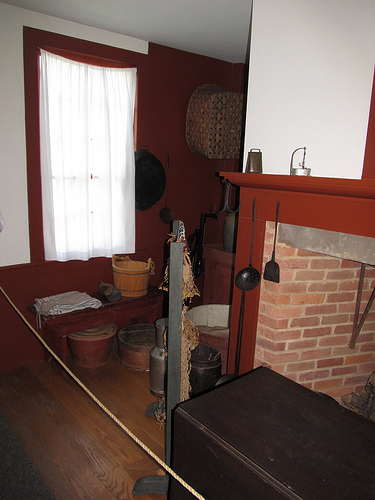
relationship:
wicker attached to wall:
[190, 66, 235, 156] [149, 67, 164, 157]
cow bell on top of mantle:
[292, 139, 322, 176] [218, 194, 363, 232]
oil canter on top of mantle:
[232, 149, 271, 180] [218, 194, 363, 232]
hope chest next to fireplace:
[192, 405, 332, 468] [247, 250, 362, 400]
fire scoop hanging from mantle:
[300, 260, 369, 396] [218, 194, 363, 232]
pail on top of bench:
[112, 260, 157, 298] [66, 303, 156, 322]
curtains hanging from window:
[33, 43, 143, 261] [48, 125, 156, 167]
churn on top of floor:
[116, 336, 178, 389] [1, 389, 150, 433]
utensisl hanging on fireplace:
[222, 198, 340, 316] [247, 250, 362, 400]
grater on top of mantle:
[338, 133, 363, 197] [218, 194, 363, 232]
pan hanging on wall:
[112, 143, 167, 206] [149, 67, 164, 157]